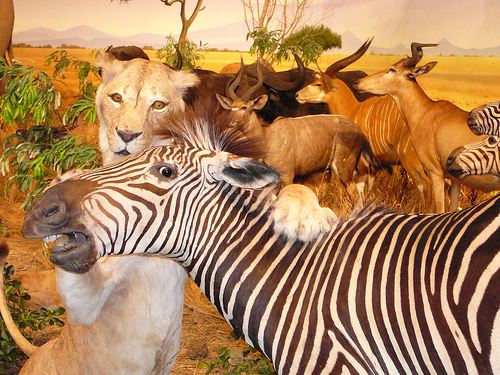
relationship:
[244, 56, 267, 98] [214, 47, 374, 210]
antler on antelope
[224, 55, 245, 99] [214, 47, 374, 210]
antler on antelope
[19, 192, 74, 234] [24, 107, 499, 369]
nose of zebra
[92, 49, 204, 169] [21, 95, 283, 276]
lion head above zebra head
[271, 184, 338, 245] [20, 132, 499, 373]
paw on zebra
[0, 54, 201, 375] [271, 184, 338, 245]
cat has paw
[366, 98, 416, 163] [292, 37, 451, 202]
stripes on animal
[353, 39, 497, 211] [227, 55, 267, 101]
antelope with antlers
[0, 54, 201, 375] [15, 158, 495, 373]
cat attacking zebra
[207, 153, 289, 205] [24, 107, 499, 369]
ears on zebra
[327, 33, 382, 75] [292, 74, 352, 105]
horns on top of head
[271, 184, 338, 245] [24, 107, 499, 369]
paw on back of zebra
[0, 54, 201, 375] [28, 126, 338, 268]
cat on a zebra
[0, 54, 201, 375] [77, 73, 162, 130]
cat with eyes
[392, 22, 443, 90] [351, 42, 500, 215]
horns on antelope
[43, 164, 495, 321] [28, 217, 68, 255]
zebra with mouth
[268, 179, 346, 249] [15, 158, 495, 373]
paw on zebra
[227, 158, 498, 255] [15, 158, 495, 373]
back of zebra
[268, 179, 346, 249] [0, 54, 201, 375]
paw of cat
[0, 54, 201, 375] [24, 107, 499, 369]
cat attacking zebra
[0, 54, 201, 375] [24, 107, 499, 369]
cat jumping on zebra